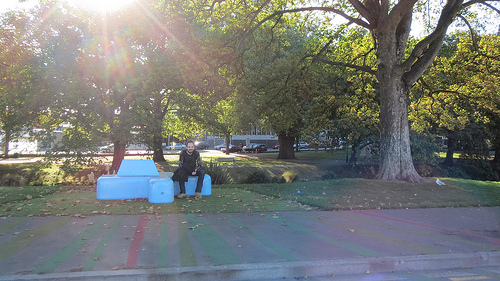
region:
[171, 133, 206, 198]
Person seated on a blue bench.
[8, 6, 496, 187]
Green trees surrounding the man.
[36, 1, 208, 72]
Sun shining through the trees.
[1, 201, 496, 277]
Sidewalk with colorful stripes.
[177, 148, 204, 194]
Person wearing black shirt and blue jeans.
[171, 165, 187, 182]
Person has dark jacket on his lap.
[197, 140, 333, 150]
Many cars parked in the building's parking lot.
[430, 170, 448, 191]
White bird standing on the grass.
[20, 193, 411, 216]
Dead leaves falling on the ground.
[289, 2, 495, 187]
Tall tree with many branches.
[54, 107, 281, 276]
a person sitting on a bench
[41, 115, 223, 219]
a person sitting on a structure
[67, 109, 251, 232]
a person sitting on a blue structure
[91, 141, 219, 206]
a person sitting outside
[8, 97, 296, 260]
a structure on the grass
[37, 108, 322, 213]
a blue structure outside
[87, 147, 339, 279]
a blue structure in front of the sidewalk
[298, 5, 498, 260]
a large tree with no leavves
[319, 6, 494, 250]
a large tree with branches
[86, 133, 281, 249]
a man on a structure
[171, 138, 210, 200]
man sitting on blue bench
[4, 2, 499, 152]
green leaves on trees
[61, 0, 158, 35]
sun shining through treeds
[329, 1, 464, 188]
big tall tree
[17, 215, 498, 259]
stripes on ground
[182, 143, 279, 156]
cars parked in distance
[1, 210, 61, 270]
yellow stripes on ground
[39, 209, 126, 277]
green stripes on ground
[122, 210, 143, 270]
red stripe on ground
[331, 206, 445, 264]
yellow stripes on ground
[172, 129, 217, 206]
the man is sitting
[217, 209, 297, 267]
the stripe is green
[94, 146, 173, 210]
the bench is blue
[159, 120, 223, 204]
the man is sitting on the bench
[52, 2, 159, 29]
the sun is shining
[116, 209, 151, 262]
the stripe is red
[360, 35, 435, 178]
the tree is thick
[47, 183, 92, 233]
the leaves are brown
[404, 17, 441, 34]
the sky is gray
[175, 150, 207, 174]
the shirt is black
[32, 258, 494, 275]
concrete street curb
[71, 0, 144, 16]
sun shining through the branches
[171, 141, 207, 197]
man sitting in the park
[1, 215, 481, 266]
colored stripes on the sidewalk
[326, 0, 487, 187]
mature tree in the park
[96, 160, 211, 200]
blue sitting area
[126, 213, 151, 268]
red stripe on the sidewalk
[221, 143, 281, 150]
cars parked in the background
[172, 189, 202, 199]
man wearing work boots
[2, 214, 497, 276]
wide concrete sidewalk